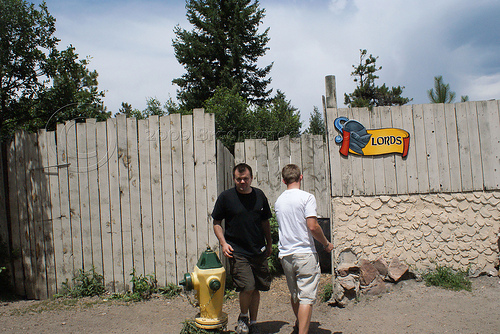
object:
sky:
[10, 0, 485, 126]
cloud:
[18, 0, 485, 126]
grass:
[417, 260, 474, 294]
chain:
[182, 286, 216, 310]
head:
[230, 160, 253, 192]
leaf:
[238, 95, 242, 101]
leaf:
[224, 110, 230, 115]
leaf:
[227, 104, 231, 110]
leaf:
[211, 101, 216, 105]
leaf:
[251, 122, 254, 124]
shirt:
[273, 186, 322, 260]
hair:
[230, 160, 254, 180]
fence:
[0, 71, 481, 299]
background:
[1, 0, 484, 300]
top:
[194, 245, 223, 269]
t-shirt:
[271, 187, 321, 260]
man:
[272, 161, 335, 331]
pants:
[280, 251, 321, 303]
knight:
[331, 112, 372, 157]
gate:
[1, 72, 484, 296]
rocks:
[348, 222, 418, 286]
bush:
[59, 236, 161, 328]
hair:
[285, 158, 297, 180]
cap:
[195, 235, 216, 254]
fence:
[45, 83, 208, 246]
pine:
[184, 33, 310, 104]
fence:
[61, 107, 171, 241]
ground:
[5, 286, 498, 334]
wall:
[334, 190, 499, 280]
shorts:
[216, 235, 281, 296]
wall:
[321, 101, 496, 201]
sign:
[330, 111, 416, 163]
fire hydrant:
[175, 242, 231, 330]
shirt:
[209, 182, 275, 253]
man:
[209, 160, 286, 331]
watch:
[321, 237, 331, 253]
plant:
[411, 253, 482, 297]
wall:
[317, 84, 498, 300]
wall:
[11, 110, 239, 310]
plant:
[53, 256, 183, 306]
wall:
[9, 73, 497, 285]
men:
[215, 155, 337, 332]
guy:
[262, 152, 332, 327]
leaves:
[179, 2, 291, 133]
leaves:
[262, 93, 288, 124]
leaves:
[175, 8, 270, 128]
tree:
[165, 0, 298, 143]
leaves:
[14, 49, 113, 137]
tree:
[0, 8, 100, 131]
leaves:
[9, 10, 100, 113]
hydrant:
[180, 240, 233, 330]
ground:
[0, 246, 500, 332]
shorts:
[272, 245, 327, 305]